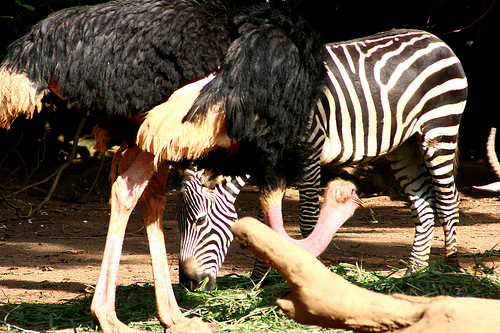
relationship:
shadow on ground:
[20, 259, 70, 326] [3, 195, 498, 331]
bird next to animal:
[0, 1, 370, 333] [174, 28, 467, 291]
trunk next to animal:
[227, 207, 432, 331] [174, 24, 468, 291]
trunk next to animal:
[227, 207, 432, 331] [1, 4, 367, 332]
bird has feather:
[6, 1, 274, 330] [67, 42, 85, 59]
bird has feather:
[6, 1, 274, 330] [98, 12, 117, 35]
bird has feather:
[6, 1, 274, 330] [141, 22, 162, 42]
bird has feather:
[6, 1, 274, 330] [182, 68, 228, 126]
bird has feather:
[6, 1, 274, 330] [260, 41, 290, 76]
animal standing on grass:
[1, 4, 500, 332] [29, 272, 483, 327]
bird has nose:
[0, 1, 370, 333] [351, 195, 365, 209]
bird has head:
[0, 1, 370, 333] [320, 179, 367, 217]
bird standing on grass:
[0, 1, 370, 333] [4, 257, 497, 331]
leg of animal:
[294, 164, 320, 236] [174, 28, 467, 291]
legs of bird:
[80, 149, 190, 331] [0, 1, 370, 333]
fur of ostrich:
[4, 72, 47, 126] [0, 3, 318, 320]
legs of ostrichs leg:
[88, 149, 191, 323] [145, 249, 183, 333]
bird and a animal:
[0, 1, 370, 333] [174, 28, 467, 291]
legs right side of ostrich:
[88, 149, 191, 323] [0, 3, 318, 320]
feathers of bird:
[6, 4, 327, 183] [0, 1, 370, 333]